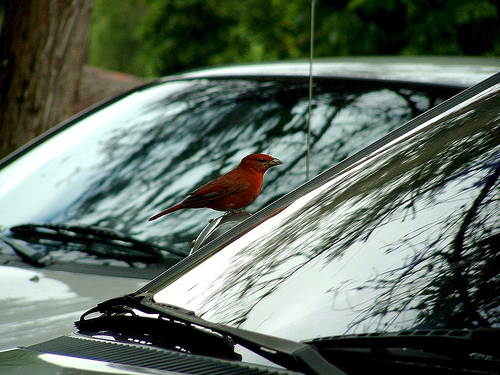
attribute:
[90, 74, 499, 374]
screen — shiny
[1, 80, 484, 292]
window — large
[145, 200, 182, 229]
feathers — long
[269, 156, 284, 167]
beak — small, pointy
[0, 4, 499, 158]
trees — tall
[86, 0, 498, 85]
leaves — green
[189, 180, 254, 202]
feathers — red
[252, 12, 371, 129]
antennae — small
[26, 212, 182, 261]
wipers — windshield, laying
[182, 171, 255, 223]
feathers — red